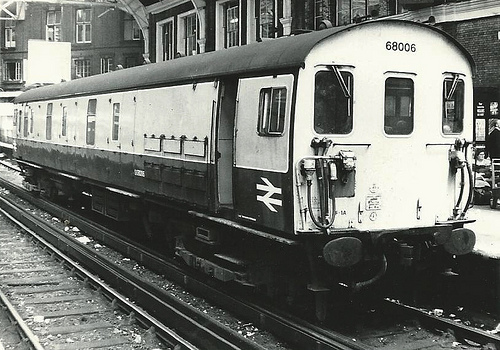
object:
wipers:
[330, 62, 352, 96]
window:
[314, 62, 356, 135]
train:
[4, 19, 300, 240]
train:
[63, 17, 478, 322]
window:
[44, 103, 52, 138]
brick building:
[21, 7, 121, 70]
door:
[151, 70, 261, 191]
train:
[74, 87, 479, 312]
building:
[111, 0, 498, 210]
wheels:
[213, 252, 274, 302]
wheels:
[165, 225, 204, 280]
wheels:
[35, 181, 55, 203]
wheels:
[21, 171, 36, 191]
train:
[176, 70, 476, 314]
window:
[378, 72, 417, 137]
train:
[288, 17, 473, 309]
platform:
[459, 201, 499, 263]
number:
[386, 39, 417, 51]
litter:
[28, 204, 102, 254]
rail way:
[2, 158, 361, 348]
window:
[245, 87, 315, 128]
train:
[114, 14, 499, 285]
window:
[112, 102, 119, 139]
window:
[85, 97, 95, 144]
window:
[46, 102, 52, 139]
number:
[378, 36, 427, 57]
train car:
[11, 17, 473, 328]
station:
[115, 2, 499, 206]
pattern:
[251, 171, 288, 198]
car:
[12, 21, 218, 281]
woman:
[466, 145, 495, 202]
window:
[60, 104, 68, 135]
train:
[14, 15, 479, 176]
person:
[483, 117, 496, 187]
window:
[440, 72, 468, 132]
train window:
[83, 97, 102, 147]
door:
[210, 64, 242, 222]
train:
[6, 22, 490, 335]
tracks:
[2, 172, 111, 347]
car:
[20, 57, 498, 233]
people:
[473, 117, 498, 180]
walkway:
[464, 200, 498, 242]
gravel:
[13, 262, 286, 337]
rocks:
[237, 257, 499, 334]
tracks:
[10, 190, 414, 348]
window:
[174, 10, 206, 63]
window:
[153, 12, 175, 67]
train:
[15, 36, 483, 346]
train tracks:
[20, 295, 454, 346]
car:
[17, 16, 477, 326]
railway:
[0, 158, 499, 348]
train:
[145, 37, 497, 215]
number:
[391, 41, 462, 71]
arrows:
[246, 169, 297, 218]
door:
[207, 80, 242, 210]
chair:
[470, 165, 495, 204]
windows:
[36, 0, 99, 52]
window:
[314, 71, 352, 140]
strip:
[2, 139, 137, 285]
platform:
[470, 193, 492, 229]